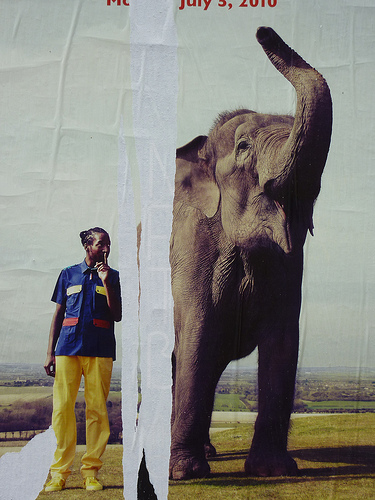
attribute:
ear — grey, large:
[174, 133, 219, 218]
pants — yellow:
[49, 356, 111, 480]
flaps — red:
[56, 316, 115, 334]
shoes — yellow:
[43, 471, 109, 488]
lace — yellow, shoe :
[46, 471, 65, 486]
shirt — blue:
[62, 266, 109, 345]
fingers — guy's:
[92, 248, 111, 283]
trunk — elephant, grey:
[242, 20, 335, 212]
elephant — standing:
[174, 22, 333, 489]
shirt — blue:
[39, 256, 129, 364]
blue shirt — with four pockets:
[47, 262, 119, 363]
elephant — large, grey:
[112, 81, 324, 417]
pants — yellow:
[35, 351, 127, 430]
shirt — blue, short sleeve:
[40, 267, 135, 335]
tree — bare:
[11, 400, 158, 441]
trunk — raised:
[221, 20, 352, 157]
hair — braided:
[81, 224, 114, 258]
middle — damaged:
[117, 220, 171, 498]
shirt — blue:
[44, 258, 125, 365]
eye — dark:
[231, 135, 260, 156]